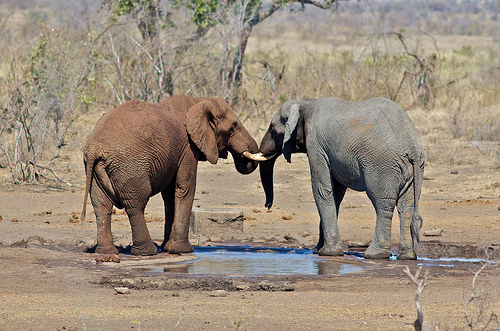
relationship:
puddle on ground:
[109, 236, 394, 291] [42, 216, 495, 328]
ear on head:
[273, 106, 310, 166] [254, 96, 306, 213]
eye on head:
[227, 116, 244, 138] [192, 94, 259, 176]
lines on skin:
[92, 126, 191, 183] [71, 80, 263, 252]